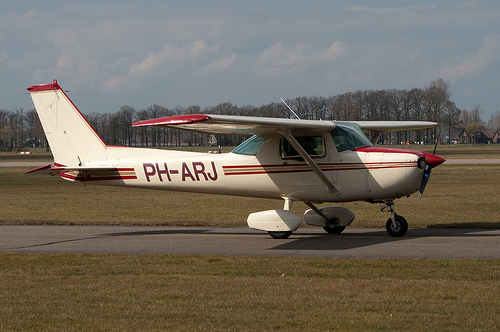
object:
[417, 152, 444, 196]
propeller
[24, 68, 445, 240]
aiplane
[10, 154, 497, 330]
grass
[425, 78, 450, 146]
trees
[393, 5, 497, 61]
sky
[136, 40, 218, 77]
clouds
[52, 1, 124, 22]
sky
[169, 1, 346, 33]
sky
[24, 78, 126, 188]
tail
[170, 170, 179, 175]
letters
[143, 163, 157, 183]
letter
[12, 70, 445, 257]
plane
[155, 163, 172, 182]
letter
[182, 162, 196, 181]
letter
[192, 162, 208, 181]
letter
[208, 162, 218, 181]
letter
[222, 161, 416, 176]
stripe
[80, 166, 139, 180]
stripe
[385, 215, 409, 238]
wheel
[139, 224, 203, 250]
roadway